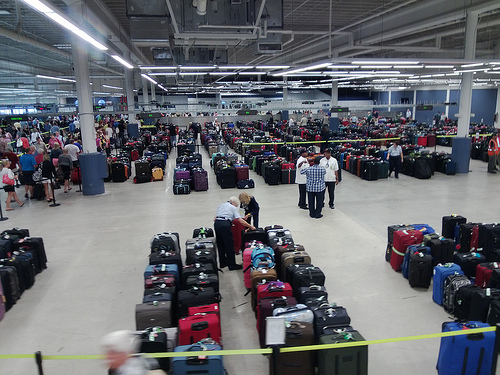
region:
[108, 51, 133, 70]
an overhead light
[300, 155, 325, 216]
A person in a blue and white shirt talking to 2 other people.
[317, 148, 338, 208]
A person in a white shirt talking to 2 other people.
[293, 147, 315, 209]
A person in a white shirt talking to 2 other people.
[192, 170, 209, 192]
A purple suitcase.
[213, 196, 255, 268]
A person bending to grab a suitcase.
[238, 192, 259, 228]
A person bending down.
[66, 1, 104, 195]
A concrete pole.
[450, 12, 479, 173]
A concrete pole.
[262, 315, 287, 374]
A white sign.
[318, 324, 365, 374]
a briefcase in an airport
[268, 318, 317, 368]
a briefcase in an airport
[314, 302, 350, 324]
a briefcase in an airport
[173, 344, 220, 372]
a briefcase in an airport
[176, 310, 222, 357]
a briefcase in an airport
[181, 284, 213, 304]
a briefcase in an airport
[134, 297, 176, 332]
a briefcase in an airport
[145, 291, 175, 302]
a briefcase in an airport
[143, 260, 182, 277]
a briefcase in an airport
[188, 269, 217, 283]
a briefcase in an airport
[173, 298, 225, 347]
one hot pink & black suitcase in front of a plain hot pink suitcase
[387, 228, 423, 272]
one roundish burgundy suitcase with something that looks like a grey rope belt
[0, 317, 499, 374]
one yellow non-velvet rope for containing luggage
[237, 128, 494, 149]
another two non-velvet yellow ropes for the same reason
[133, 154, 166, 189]
small beige suitcase beside & before two large black pieces of luggage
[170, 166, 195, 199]
purple suitcase behind brown+light blue smaller suitcase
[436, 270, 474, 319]
black+white patterned suitcase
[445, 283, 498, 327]
roundish black luggage w/ white trim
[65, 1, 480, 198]
4 off-white concrete poles with steel blue bases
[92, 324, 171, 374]
blurry man @ front w/ white hair, white garment, white moustache, walking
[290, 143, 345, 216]
Group of men talking.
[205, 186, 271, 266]
Two people searching bags.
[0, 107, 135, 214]
Large group of people.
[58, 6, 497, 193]
Concrete posts in the building.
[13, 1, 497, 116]
Lots of light above.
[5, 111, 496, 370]
Many groups of luggage on the floor.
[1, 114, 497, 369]
Concrete floor in the building.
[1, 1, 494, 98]
Lots of pipes in the ceiling.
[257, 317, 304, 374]
Sign by one of the groups of luggage.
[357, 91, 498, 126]
Blue walls in the building.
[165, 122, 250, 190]
Suitcases lined up in rows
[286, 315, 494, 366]
Yellow barrier ribbon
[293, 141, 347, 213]
A group of men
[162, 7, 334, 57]
Pipes running through a ceiling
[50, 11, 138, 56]
Hanging fluorescent lights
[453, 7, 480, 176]
A tall support post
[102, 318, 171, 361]
A person with white hair walking past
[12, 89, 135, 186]
Long lines of people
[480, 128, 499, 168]
A man in an orange vest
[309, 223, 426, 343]
An aisle between rows of suitcases